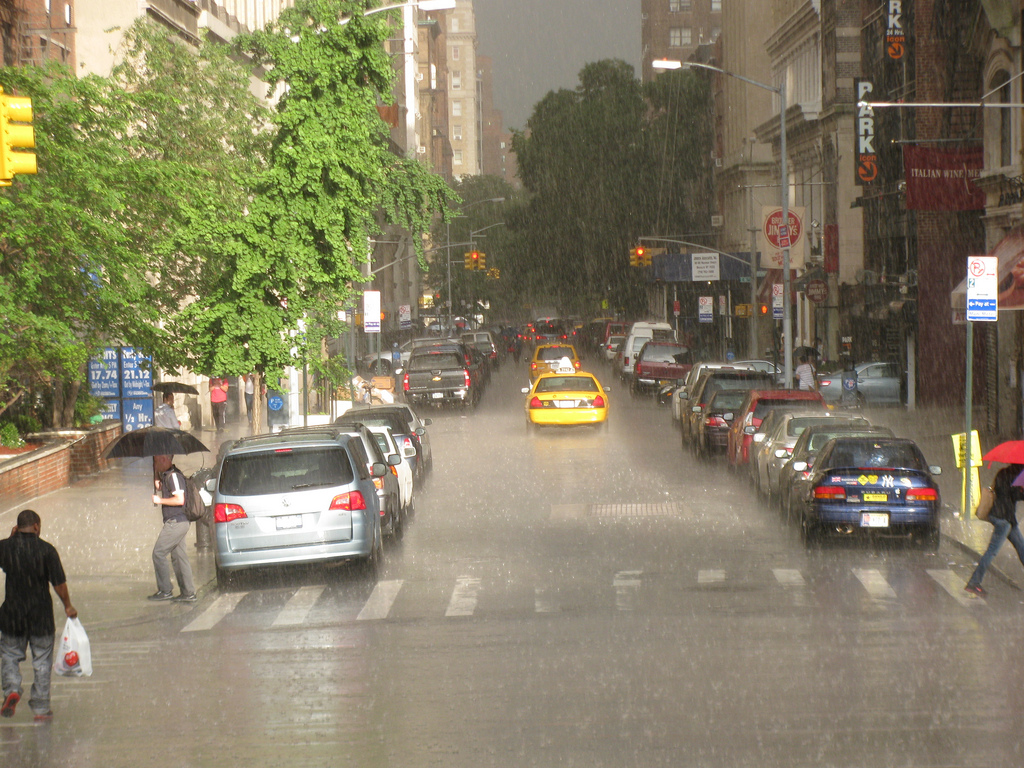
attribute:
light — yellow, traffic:
[1, 74, 51, 191]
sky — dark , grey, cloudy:
[490, 1, 672, 118]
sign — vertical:
[814, 68, 907, 250]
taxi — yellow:
[527, 348, 607, 459]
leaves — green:
[104, 4, 455, 378]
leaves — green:
[28, 12, 430, 373]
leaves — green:
[176, 173, 378, 275]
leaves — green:
[135, 44, 213, 151]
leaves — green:
[316, 24, 397, 124]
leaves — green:
[571, 67, 643, 178]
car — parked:
[214, 419, 407, 560]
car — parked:
[361, 415, 454, 513]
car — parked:
[828, 426, 954, 554]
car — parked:
[677, 325, 786, 468]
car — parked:
[627, 320, 694, 401]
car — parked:
[409, 337, 487, 431]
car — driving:
[508, 351, 625, 431]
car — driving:
[526, 335, 593, 375]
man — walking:
[12, 482, 92, 727]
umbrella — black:
[68, 398, 235, 459]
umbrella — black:
[96, 404, 218, 471]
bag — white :
[45, 603, 117, 705]